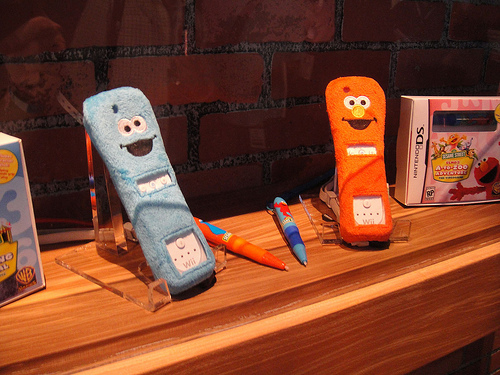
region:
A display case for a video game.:
[5, 17, 496, 329]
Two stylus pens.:
[190, 177, 315, 277]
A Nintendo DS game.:
[395, 90, 495, 225]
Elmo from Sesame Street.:
[446, 152, 496, 189]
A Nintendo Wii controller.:
[320, 75, 411, 256]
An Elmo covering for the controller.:
[317, 75, 412, 260]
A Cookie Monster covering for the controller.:
[70, 80, 230, 300]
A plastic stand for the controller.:
[61, 131, 186, 311]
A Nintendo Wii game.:
[0, 130, 40, 300]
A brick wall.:
[115, 20, 296, 130]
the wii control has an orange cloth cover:
[324, 74, 394, 242]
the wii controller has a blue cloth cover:
[82, 85, 214, 295]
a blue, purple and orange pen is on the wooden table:
[270, 197, 307, 267]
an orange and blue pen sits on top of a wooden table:
[192, 216, 288, 271]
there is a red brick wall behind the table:
[0, 0, 498, 250]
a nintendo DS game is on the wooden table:
[395, 95, 499, 205]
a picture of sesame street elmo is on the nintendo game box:
[447, 156, 498, 201]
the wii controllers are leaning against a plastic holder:
[56, 163, 227, 312]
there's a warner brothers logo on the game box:
[14, 265, 36, 284]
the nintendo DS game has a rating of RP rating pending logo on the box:
[424, 186, 435, 199]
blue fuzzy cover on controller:
[78, 86, 218, 296]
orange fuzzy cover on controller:
[323, 74, 393, 247]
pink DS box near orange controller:
[396, 91, 498, 209]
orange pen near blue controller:
[192, 214, 290, 274]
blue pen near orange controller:
[268, 194, 312, 269]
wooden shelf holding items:
[1, 179, 499, 373]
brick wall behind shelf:
[0, 2, 499, 230]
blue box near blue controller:
[1, 128, 48, 306]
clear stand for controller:
[46, 85, 228, 313]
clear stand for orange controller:
[296, 150, 413, 247]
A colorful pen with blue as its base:
[275, 205, 312, 262]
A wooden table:
[257, 297, 407, 338]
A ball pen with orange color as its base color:
[203, 226, 280, 271]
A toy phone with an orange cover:
[324, 75, 396, 245]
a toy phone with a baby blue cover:
[84, 90, 212, 290]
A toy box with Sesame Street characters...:
[398, 84, 498, 200]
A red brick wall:
[198, 41, 274, 161]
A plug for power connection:
[79, 216, 141, 243]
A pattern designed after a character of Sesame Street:
[325, 78, 390, 133]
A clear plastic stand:
[111, 282, 174, 304]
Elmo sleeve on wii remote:
[331, 76, 400, 240]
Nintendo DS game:
[408, 97, 498, 203]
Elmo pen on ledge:
[267, 193, 325, 275]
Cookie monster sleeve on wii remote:
[83, 91, 235, 303]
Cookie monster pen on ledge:
[186, 210, 294, 277]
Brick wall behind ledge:
[0, 1, 493, 145]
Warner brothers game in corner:
[2, 137, 43, 289]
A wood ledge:
[5, 253, 495, 369]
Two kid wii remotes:
[83, 66, 405, 258]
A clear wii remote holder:
[70, 117, 173, 317]